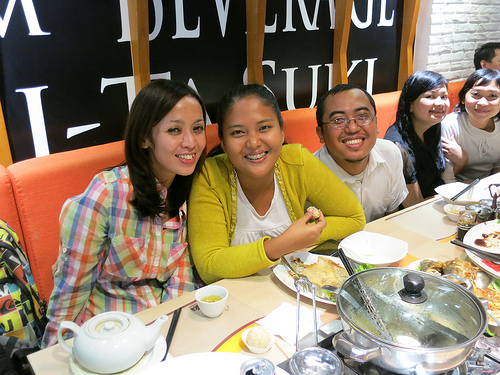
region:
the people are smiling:
[75, 50, 492, 204]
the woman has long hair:
[124, 82, 211, 240]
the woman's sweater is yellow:
[187, 151, 382, 281]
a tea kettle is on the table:
[25, 290, 226, 370]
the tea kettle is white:
[28, 285, 175, 372]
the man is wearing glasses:
[317, 92, 391, 153]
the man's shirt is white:
[311, 140, 435, 230]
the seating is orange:
[2, 64, 482, 291]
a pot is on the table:
[330, 264, 498, 374]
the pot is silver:
[310, 248, 465, 369]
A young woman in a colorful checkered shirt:
[46, 79, 205, 339]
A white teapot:
[46, 290, 174, 374]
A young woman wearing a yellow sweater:
[180, 75, 371, 285]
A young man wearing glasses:
[305, 76, 423, 233]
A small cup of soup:
[187, 272, 244, 329]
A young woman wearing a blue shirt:
[375, 66, 465, 208]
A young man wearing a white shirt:
[302, 75, 417, 233]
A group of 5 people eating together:
[42, 61, 494, 352]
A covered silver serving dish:
[329, 258, 487, 372]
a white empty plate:
[334, 218, 419, 274]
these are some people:
[93, 64, 476, 220]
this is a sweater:
[293, 156, 318, 195]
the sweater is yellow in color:
[296, 153, 307, 196]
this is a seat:
[15, 180, 45, 227]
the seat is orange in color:
[12, 177, 41, 226]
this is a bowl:
[192, 285, 223, 315]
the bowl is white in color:
[206, 302, 218, 314]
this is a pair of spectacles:
[322, 117, 379, 127]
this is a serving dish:
[331, 273, 483, 372]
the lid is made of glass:
[355, 291, 377, 312]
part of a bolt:
[401, 275, 420, 295]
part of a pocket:
[117, 249, 137, 274]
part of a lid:
[363, 280, 390, 323]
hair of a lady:
[127, 172, 171, 234]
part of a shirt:
[107, 224, 144, 280]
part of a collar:
[241, 193, 268, 222]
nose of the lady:
[242, 132, 252, 157]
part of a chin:
[341, 142, 362, 162]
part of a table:
[179, 317, 206, 342]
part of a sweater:
[198, 197, 229, 238]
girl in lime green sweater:
[185, 83, 364, 276]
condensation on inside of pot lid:
[339, 262, 482, 350]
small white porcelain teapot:
[53, 308, 168, 369]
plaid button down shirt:
[59, 199, 174, 301]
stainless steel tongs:
[289, 266, 323, 357]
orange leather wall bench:
[8, 149, 124, 256]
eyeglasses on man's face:
[315, 86, 379, 172]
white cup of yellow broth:
[194, 281, 230, 318]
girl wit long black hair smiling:
[385, 62, 451, 206]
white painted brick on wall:
[438, 5, 474, 65]